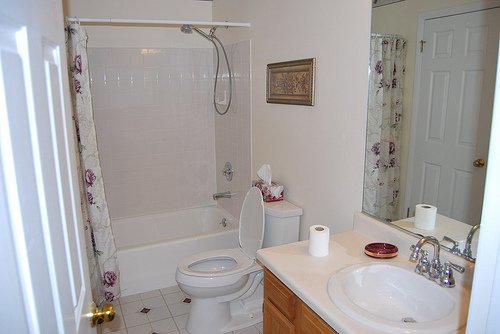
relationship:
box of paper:
[252, 162, 283, 200] [257, 163, 276, 187]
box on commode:
[252, 162, 283, 200] [144, 184, 303, 332]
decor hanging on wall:
[264, 57, 320, 114] [288, 124, 368, 182]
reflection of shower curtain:
[361, 0, 500, 260] [57, 10, 131, 307]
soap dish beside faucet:
[362, 241, 397, 259] [408, 235, 443, 279]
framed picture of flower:
[265, 57, 313, 105] [278, 69, 295, 92]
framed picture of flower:
[265, 57, 313, 105] [297, 73, 307, 90]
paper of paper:
[308, 225, 330, 257] [308, 225, 330, 257]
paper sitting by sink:
[308, 225, 330, 257] [334, 251, 454, 333]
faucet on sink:
[408, 234, 464, 287] [327, 257, 471, 332]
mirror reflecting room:
[361, 0, 500, 264] [3, 2, 496, 332]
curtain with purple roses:
[63, 23, 129, 306] [68, 52, 85, 95]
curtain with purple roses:
[63, 23, 129, 306] [81, 165, 118, 301]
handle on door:
[73, 293, 140, 332] [2, 1, 103, 331]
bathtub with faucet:
[123, 197, 253, 289] [211, 189, 232, 205]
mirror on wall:
[349, 5, 476, 269] [214, 2, 499, 258]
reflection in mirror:
[382, 9, 473, 229] [361, 0, 500, 264]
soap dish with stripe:
[364, 242, 399, 259] [366, 250, 396, 258]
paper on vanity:
[308, 225, 330, 257] [260, 0, 497, 329]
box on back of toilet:
[252, 180, 284, 203] [174, 184, 304, 331]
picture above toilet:
[262, 59, 318, 107] [83, 39, 498, 297]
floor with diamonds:
[148, 285, 195, 322] [132, 298, 196, 312]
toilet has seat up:
[168, 185, 298, 332] [168, 172, 270, 300]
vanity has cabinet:
[249, 234, 378, 332] [256, 259, 337, 334]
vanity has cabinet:
[249, 234, 378, 332] [255, 299, 297, 331]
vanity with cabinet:
[249, 234, 378, 332] [256, 259, 337, 334]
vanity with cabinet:
[249, 234, 378, 332] [255, 299, 297, 331]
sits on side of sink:
[178, 240, 255, 291] [335, 259, 465, 333]